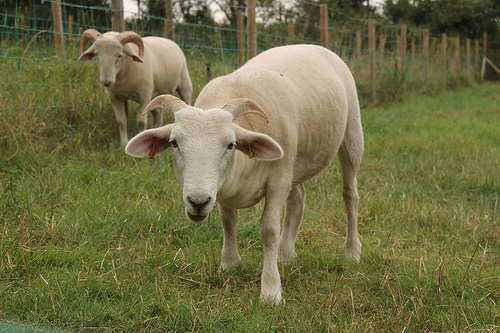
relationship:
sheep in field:
[133, 40, 378, 302] [0, 81, 497, 331]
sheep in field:
[75, 24, 195, 149] [0, 81, 497, 331]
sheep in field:
[133, 40, 378, 302] [2, 45, 497, 332]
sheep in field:
[75, 24, 195, 149] [2, 45, 497, 332]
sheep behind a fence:
[133, 40, 378, 302] [0, 12, 498, 141]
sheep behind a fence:
[75, 27, 193, 149] [0, 12, 498, 141]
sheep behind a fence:
[75, 27, 193, 149] [4, 3, 498, 103]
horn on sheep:
[219, 97, 270, 124] [131, 47, 393, 297]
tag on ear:
[144, 133, 161, 160] [120, 118, 174, 163]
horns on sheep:
[76, 29, 147, 61] [75, 27, 193, 149]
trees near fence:
[2, 3, 499, 45] [2, 24, 497, 78]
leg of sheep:
[337, 119, 364, 262] [122, 42, 366, 305]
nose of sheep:
[188, 192, 210, 210] [122, 42, 366, 305]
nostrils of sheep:
[172, 193, 220, 215] [109, 60, 350, 270]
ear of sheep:
[229, 132, 282, 167] [149, 38, 351, 307]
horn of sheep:
[214, 98, 271, 121] [123, 43, 365, 308]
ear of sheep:
[123, 125, 166, 157] [123, 43, 365, 308]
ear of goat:
[74, 46, 96, 61] [76, 29, 189, 136]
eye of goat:
[166, 137, 181, 149] [113, 38, 369, 316]